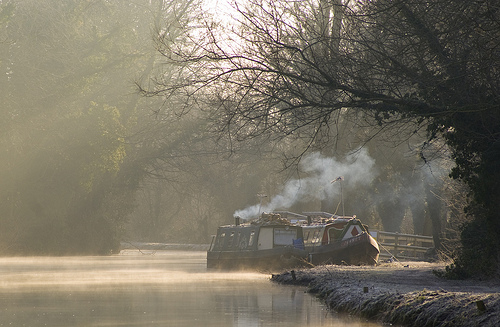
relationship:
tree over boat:
[227, 15, 455, 144] [204, 192, 388, 272]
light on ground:
[328, 258, 440, 271] [329, 260, 459, 292]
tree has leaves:
[2, 7, 211, 256] [2, 2, 199, 242]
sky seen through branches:
[3, 4, 497, 202] [137, 2, 497, 159]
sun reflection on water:
[0, 249, 276, 289] [1, 241, 376, 325]